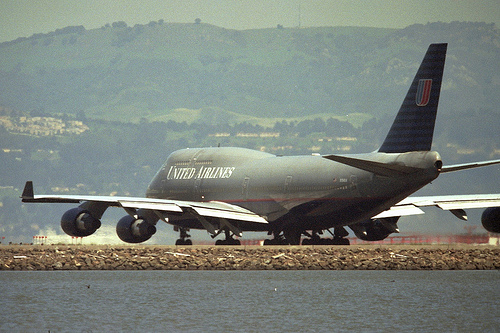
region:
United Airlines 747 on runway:
[101, 96, 469, 247]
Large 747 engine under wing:
[52, 205, 99, 231]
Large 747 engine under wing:
[115, 180, 157, 248]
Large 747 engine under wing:
[355, 205, 412, 251]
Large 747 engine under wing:
[475, 196, 497, 226]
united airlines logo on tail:
[413, 74, 438, 119]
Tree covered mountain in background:
[25, 15, 483, 245]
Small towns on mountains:
[0, 88, 89, 153]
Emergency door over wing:
[237, 165, 253, 202]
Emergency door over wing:
[276, 170, 301, 205]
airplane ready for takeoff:
[13, 44, 491, 295]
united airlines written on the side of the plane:
[161, 159, 242, 186]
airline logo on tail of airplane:
[405, 73, 441, 118]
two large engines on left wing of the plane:
[53, 193, 173, 249]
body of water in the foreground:
[29, 270, 451, 332]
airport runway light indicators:
[22, 225, 96, 254]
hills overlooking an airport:
[25, 18, 480, 190]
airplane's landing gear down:
[176, 225, 251, 251]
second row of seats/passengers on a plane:
[163, 149, 221, 172]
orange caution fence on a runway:
[404, 227, 491, 249]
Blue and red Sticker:
[406, 68, 439, 120]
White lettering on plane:
[158, 163, 240, 185]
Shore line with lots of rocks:
[40, 258, 482, 285]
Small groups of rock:
[5, 246, 37, 274]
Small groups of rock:
[40, 247, 85, 277]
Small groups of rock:
[88, 246, 137, 271]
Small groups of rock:
[140, 243, 199, 268]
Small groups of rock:
[187, 240, 254, 274]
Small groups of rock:
[260, 240, 322, 271]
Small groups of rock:
[340, 246, 406, 275]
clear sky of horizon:
[2, 1, 499, 38]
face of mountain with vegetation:
[0, 16, 495, 184]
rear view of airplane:
[20, 42, 496, 242]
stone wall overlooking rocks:
[2, 247, 498, 327]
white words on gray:
[166, 165, 235, 180]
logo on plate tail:
[381, 41, 446, 153]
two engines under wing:
[19, 178, 266, 243]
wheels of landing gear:
[172, 233, 354, 248]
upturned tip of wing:
[18, 180, 57, 203]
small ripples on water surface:
[9, 268, 497, 332]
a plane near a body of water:
[13, 28, 498, 316]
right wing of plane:
[373, 180, 499, 226]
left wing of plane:
[18, 172, 264, 221]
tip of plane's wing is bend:
[15, 168, 71, 213]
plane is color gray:
[8, 28, 495, 255]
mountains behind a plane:
[0, 5, 490, 158]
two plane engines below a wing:
[48, 200, 168, 246]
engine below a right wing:
[341, 208, 413, 246]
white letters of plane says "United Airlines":
[144, 129, 266, 214]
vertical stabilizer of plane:
[376, 37, 450, 150]